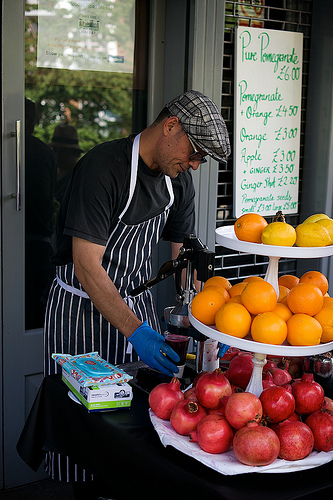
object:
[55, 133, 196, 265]
shirt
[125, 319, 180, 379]
glove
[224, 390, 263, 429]
pomegranate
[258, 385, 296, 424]
pomegranate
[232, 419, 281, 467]
pomegranate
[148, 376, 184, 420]
pomegranate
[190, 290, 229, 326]
orange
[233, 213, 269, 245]
orange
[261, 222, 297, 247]
lemon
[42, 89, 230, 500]
man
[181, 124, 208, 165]
sunglasses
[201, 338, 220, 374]
cup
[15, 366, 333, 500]
tablecloth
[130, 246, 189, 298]
handle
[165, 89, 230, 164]
hat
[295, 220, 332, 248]
lemon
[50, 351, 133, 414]
wipe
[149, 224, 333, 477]
stand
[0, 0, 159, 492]
door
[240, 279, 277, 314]
orange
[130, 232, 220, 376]
juicer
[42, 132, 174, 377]
apron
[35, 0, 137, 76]
menu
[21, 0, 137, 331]
indow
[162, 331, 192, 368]
juice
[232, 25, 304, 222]
white board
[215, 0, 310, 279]
window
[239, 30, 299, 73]
letters